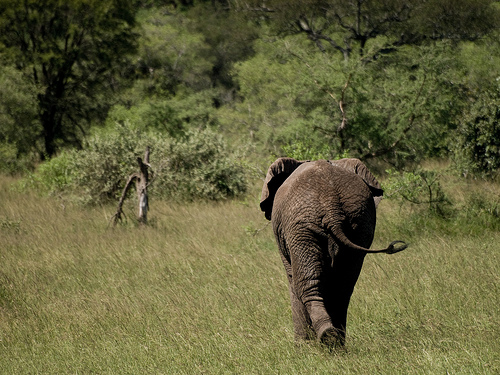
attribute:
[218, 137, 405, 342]
elephant — walking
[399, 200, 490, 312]
grass — blowing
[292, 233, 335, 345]
leg — brown 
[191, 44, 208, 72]
leaves — green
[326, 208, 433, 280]
tail — grey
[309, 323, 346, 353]
foot — elephant , grey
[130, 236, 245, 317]
yellow grass — long green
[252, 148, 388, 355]
elephant — walking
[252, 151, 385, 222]
ears — large 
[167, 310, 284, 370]
grass — green, wavy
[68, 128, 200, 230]
trees — snapped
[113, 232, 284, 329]
grass — yellow , green 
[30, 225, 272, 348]
grass — long green, yellow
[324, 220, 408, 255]
tail — brown , bushy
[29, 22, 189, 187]
tree — gloomy, Dark 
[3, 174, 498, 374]
grass —  yellow, long green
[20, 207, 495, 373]
grass — green , yellow 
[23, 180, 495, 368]
grass — long green, yellow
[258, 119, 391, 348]
elephant — large, lonely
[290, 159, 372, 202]
back — grey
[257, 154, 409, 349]
elephant — gray, grey, walking away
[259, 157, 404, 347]
elephant`s skin — wrinkled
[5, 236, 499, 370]
grass — long ,  green,  yellow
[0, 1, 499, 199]
trees — LARGE AMOUNT, thick green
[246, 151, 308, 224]
ear — grey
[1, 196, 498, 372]
grass — yellow, green, long 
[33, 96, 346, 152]
bushes — green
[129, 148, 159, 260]
stump — small bare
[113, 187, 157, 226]
stump — grey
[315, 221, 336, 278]
skin — wrinkled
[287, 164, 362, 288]
skin — wrinkled